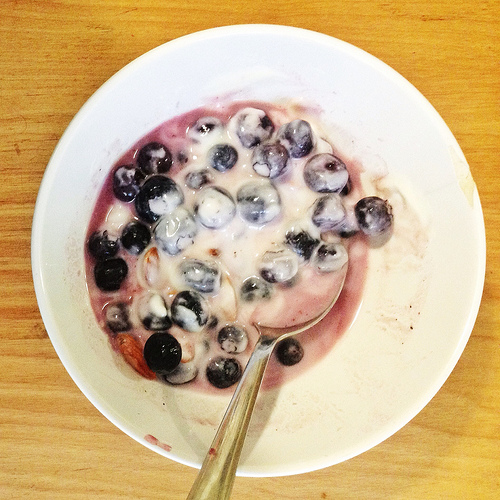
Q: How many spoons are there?
A: One.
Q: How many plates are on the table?
A: One.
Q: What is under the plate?
A: A table.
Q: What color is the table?
A: Brown.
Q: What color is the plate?
A: White.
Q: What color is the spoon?
A: Silver.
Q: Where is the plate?
A: On the table.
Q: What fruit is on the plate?
A: Blueberries.